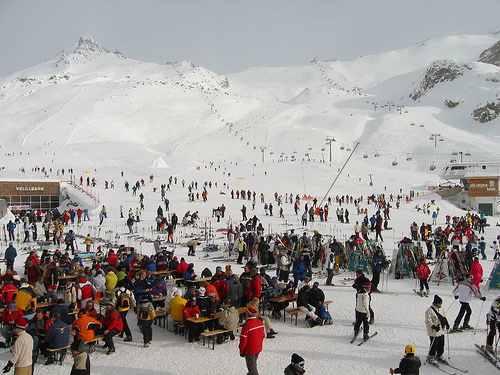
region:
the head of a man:
[239, 302, 270, 322]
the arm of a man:
[226, 325, 256, 361]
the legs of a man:
[331, 316, 387, 362]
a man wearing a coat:
[227, 282, 315, 359]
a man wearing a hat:
[240, 296, 273, 331]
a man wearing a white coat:
[413, 288, 463, 346]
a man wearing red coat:
[219, 288, 301, 373]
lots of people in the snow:
[49, 185, 361, 348]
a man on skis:
[424, 289, 471, 365]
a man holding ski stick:
[411, 295, 477, 362]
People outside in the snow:
[70, 244, 207, 313]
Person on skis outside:
[350, 276, 378, 351]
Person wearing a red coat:
[234, 306, 269, 358]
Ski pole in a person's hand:
[421, 315, 439, 363]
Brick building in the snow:
[3, 172, 59, 216]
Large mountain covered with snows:
[27, 19, 174, 111]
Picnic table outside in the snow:
[188, 308, 248, 350]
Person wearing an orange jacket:
[71, 309, 96, 341]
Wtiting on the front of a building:
[11, 183, 49, 197]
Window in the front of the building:
[37, 191, 49, 206]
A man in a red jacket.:
[238, 305, 265, 373]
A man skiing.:
[350, 280, 379, 348]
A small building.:
[1, 180, 60, 213]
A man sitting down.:
[41, 313, 69, 363]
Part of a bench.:
[201, 328, 221, 346]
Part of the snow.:
[311, 331, 336, 364]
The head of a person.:
[288, 351, 306, 371]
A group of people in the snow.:
[230, 188, 257, 199]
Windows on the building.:
[38, 195, 50, 207]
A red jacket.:
[416, 262, 430, 281]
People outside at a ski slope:
[5, 80, 485, 371]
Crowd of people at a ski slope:
[0, 55, 491, 370]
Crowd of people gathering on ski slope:
[5, 26, 490, 362]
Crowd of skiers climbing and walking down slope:
[5, 25, 491, 365]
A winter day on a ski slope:
[5, 20, 495, 365]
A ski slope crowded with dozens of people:
[2, 17, 494, 362]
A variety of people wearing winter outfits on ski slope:
[0, 170, 496, 365]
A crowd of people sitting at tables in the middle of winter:
[0, 165, 335, 370]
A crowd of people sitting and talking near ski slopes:
[0, 162, 335, 372]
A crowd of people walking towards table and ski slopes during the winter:
[0, 153, 343, 373]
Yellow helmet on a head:
[402, 343, 414, 354]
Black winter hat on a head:
[430, 293, 443, 306]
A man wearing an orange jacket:
[73, 307, 98, 352]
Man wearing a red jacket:
[238, 308, 266, 373]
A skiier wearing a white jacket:
[350, 280, 375, 342]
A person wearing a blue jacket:
[7, 218, 18, 240]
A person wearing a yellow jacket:
[169, 290, 187, 325]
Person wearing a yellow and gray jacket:
[136, 297, 156, 346]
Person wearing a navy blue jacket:
[43, 313, 70, 365]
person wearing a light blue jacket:
[97, 211, 104, 224]